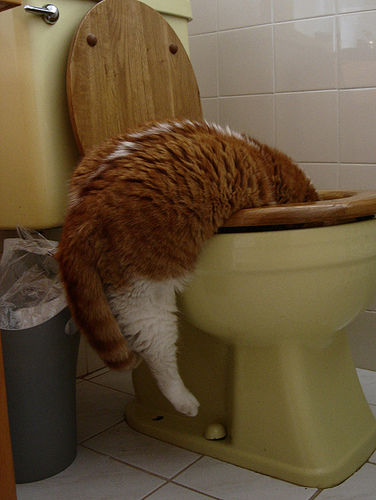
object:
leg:
[110, 258, 201, 418]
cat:
[54, 114, 320, 418]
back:
[106, 118, 246, 154]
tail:
[51, 210, 145, 372]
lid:
[65, 1, 203, 158]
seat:
[214, 191, 376, 234]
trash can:
[0, 293, 82, 487]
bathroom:
[0, 0, 376, 499]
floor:
[14, 366, 376, 499]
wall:
[183, 0, 376, 199]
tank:
[2, 0, 195, 232]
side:
[0, 0, 57, 233]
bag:
[0, 225, 69, 331]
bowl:
[176, 217, 376, 349]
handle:
[23, 4, 59, 27]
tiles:
[272, 0, 373, 166]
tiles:
[85, 440, 181, 500]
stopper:
[215, 222, 323, 234]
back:
[32, 0, 193, 230]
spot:
[152, 410, 163, 422]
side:
[125, 228, 329, 490]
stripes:
[90, 313, 113, 342]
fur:
[122, 238, 169, 332]